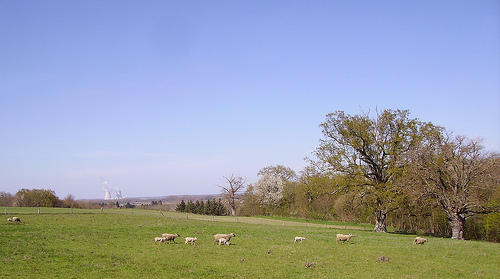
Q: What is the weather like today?
A: It is clear.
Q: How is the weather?
A: It is clear.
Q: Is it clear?
A: Yes, it is clear.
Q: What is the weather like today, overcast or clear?
A: It is clear.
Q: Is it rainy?
A: No, it is clear.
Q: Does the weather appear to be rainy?
A: No, it is clear.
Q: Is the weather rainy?
A: No, it is clear.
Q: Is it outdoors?
A: Yes, it is outdoors.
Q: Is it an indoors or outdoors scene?
A: It is outdoors.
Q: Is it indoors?
A: No, it is outdoors.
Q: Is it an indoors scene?
A: No, it is outdoors.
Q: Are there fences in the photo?
A: No, there are no fences.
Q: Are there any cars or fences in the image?
A: No, there are no fences or cars.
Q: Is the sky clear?
A: Yes, the sky is clear.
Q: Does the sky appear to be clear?
A: Yes, the sky is clear.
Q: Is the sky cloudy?
A: No, the sky is clear.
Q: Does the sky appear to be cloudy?
A: No, the sky is clear.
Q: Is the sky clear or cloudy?
A: The sky is clear.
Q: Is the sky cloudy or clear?
A: The sky is clear.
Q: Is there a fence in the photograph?
A: No, there are no fences.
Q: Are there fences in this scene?
A: No, there are no fences.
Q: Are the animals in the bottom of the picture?
A: Yes, the animals are in the bottom of the image.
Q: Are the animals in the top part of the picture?
A: No, the animals are in the bottom of the image.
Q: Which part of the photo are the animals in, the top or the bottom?
A: The animals are in the bottom of the image.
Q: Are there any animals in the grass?
A: Yes, there are animals in the grass.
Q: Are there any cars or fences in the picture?
A: No, there are no fences or cars.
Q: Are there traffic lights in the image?
A: No, there are no traffic lights.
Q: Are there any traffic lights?
A: No, there are no traffic lights.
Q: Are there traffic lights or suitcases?
A: No, there are no traffic lights or suitcases.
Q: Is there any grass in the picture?
A: Yes, there is grass.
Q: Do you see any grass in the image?
A: Yes, there is grass.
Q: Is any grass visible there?
A: Yes, there is grass.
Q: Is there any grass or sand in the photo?
A: Yes, there is grass.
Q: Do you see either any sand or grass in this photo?
A: Yes, there is grass.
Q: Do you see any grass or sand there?
A: Yes, there is grass.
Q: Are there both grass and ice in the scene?
A: No, there is grass but no ice.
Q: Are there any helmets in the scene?
A: No, there are no helmets.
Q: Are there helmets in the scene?
A: No, there are no helmets.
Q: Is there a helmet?
A: No, there are no helmets.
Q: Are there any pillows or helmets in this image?
A: No, there are no helmets or pillows.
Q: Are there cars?
A: No, there are no cars.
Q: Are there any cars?
A: No, there are no cars.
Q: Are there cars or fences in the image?
A: No, there are no cars or fences.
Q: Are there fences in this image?
A: No, there are no fences.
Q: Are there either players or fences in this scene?
A: No, there are no fences or players.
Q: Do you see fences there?
A: No, there are no fences.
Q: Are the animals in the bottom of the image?
A: Yes, the animals are in the bottom of the image.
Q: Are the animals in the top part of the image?
A: No, the animals are in the bottom of the image.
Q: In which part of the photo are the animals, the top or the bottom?
A: The animals are in the bottom of the image.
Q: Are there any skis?
A: No, there are no skis.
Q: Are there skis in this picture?
A: No, there are no skis.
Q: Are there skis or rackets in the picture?
A: No, there are no skis or rackets.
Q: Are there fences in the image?
A: No, there are no fences.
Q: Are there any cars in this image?
A: No, there are no cars.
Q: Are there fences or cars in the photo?
A: No, there are no cars or fences.